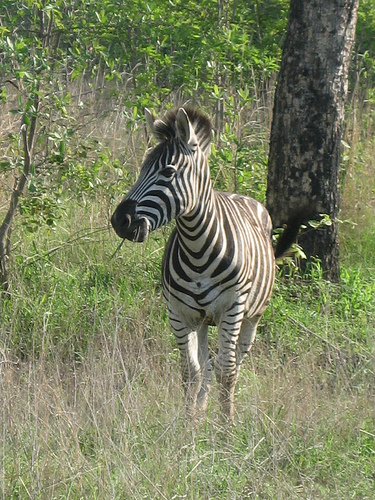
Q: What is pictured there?
A: Zebra.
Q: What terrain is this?
A: Grassland.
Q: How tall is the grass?
A: Very tall.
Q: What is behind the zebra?
A: Tree.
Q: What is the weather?
A: Fair.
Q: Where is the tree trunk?
A: Behind zebra.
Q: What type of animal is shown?
A: Zebra.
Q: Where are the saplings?
A: Behind zebra.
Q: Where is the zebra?
A: Grass field.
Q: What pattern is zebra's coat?
A: Striped.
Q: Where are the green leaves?
A: On trees.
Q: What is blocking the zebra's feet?
A: Grass.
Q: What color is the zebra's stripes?
A: Black.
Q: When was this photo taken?
A: During the day.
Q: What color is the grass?
A: Brown.